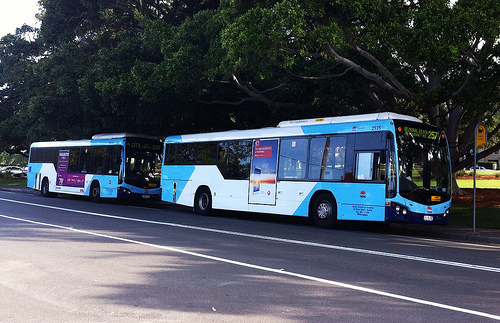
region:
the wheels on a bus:
[277, 185, 358, 225]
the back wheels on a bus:
[176, 153, 247, 238]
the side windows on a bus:
[246, 121, 360, 202]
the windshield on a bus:
[384, 105, 444, 207]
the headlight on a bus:
[376, 182, 487, 227]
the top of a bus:
[236, 74, 436, 154]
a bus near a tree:
[248, 30, 396, 161]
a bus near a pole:
[334, 122, 496, 227]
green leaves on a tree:
[179, 0, 332, 86]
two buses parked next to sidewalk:
[17, 101, 462, 238]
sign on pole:
[467, 118, 494, 230]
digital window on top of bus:
[396, 117, 447, 150]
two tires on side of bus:
[185, 173, 349, 232]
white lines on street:
[4, 211, 491, 316]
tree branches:
[327, 44, 428, 102]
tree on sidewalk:
[217, 1, 494, 196]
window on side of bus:
[347, 148, 379, 185]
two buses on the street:
[10, 117, 460, 220]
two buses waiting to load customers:
[24, 121, 458, 224]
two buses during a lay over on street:
[22, 115, 468, 233]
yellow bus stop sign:
[475, 119, 486, 234]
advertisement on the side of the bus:
[248, 138, 276, 204]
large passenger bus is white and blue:
[161, 128, 453, 226]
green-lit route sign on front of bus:
[400, 122, 445, 142]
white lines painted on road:
[120, 205, 265, 265]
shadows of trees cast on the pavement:
[69, 244, 296, 321]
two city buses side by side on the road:
[18, 109, 468, 238]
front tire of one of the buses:
[304, 197, 336, 227]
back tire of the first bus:
[189, 184, 219, 212]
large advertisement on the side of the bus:
[251, 137, 280, 209]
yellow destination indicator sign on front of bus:
[396, 119, 442, 146]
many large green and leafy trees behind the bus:
[30, 15, 487, 110]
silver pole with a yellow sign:
[468, 117, 491, 231]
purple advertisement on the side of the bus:
[55, 147, 84, 195]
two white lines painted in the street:
[203, 242, 448, 322]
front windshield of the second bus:
[126, 152, 161, 192]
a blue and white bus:
[155, 109, 470, 234]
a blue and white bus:
[23, 132, 166, 207]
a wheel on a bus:
[309, 193, 336, 225]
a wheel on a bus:
[190, 186, 213, 212]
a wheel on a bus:
[87, 181, 101, 199]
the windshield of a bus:
[391, 118, 453, 208]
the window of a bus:
[275, 132, 354, 182]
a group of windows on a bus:
[162, 138, 253, 180]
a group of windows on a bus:
[65, 143, 122, 178]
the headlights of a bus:
[390, 202, 411, 219]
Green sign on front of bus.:
[402, 124, 439, 139]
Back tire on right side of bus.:
[190, 184, 215, 214]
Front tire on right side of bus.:
[305, 187, 340, 230]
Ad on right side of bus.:
[247, 134, 282, 208]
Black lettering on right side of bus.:
[347, 202, 380, 217]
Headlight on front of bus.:
[390, 200, 412, 222]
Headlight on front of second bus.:
[118, 185, 135, 200]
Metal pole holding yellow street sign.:
[468, 120, 478, 248]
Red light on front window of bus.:
[395, 122, 402, 134]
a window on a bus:
[29, 147, 39, 163]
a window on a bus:
[38, 147, 48, 167]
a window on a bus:
[46, 143, 60, 161]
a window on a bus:
[80, 145, 99, 172]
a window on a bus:
[100, 139, 124, 174]